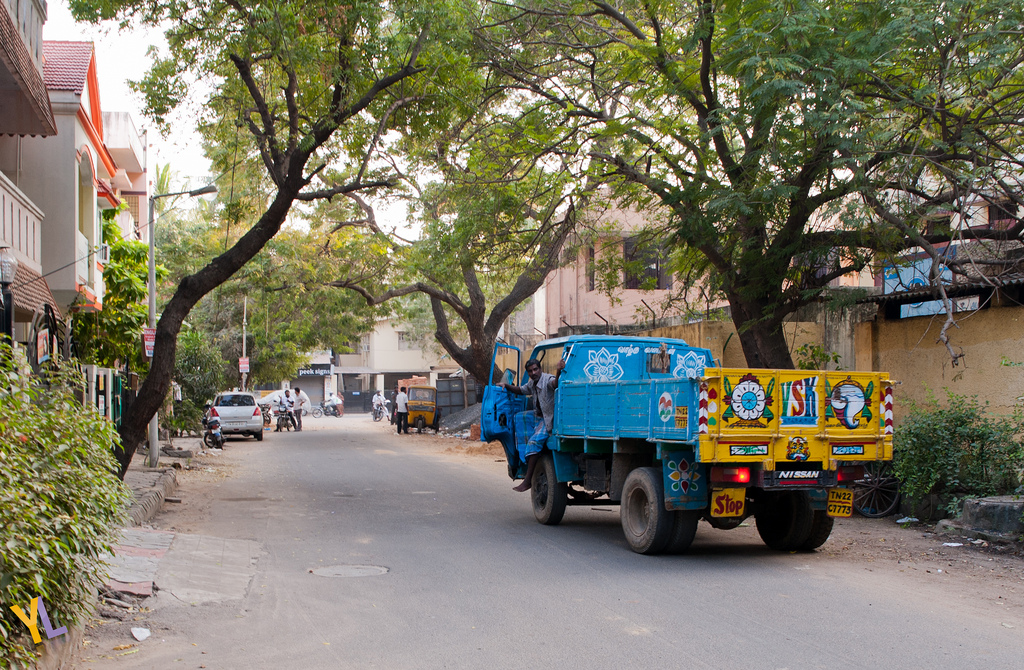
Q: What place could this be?
A: It is a road.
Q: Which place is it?
A: It is a road.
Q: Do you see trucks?
A: Yes, there is a truck.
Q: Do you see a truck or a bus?
A: Yes, there is a truck.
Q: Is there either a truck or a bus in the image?
A: Yes, there is a truck.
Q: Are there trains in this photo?
A: No, there are no trains.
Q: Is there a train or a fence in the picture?
A: No, there are no trains or fences.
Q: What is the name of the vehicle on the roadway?
A: The vehicle is a truck.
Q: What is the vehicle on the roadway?
A: The vehicle is a truck.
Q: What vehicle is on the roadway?
A: The vehicle is a truck.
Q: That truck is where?
A: The truck is on the roadway.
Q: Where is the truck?
A: The truck is on the roadway.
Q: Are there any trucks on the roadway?
A: Yes, there is a truck on the roadway.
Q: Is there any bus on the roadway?
A: No, there is a truck on the roadway.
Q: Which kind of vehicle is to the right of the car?
A: The vehicle is a truck.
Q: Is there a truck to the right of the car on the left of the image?
A: Yes, there is a truck to the right of the car.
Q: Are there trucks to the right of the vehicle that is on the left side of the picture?
A: Yes, there is a truck to the right of the car.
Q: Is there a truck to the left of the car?
A: No, the truck is to the right of the car.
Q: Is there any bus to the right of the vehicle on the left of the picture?
A: No, there is a truck to the right of the car.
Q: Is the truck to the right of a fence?
A: No, the truck is to the right of the car.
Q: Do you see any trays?
A: No, there are no trays.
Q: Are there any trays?
A: No, there are no trays.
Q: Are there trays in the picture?
A: No, there are no trays.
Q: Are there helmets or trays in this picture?
A: No, there are no trays or helmets.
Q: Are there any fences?
A: No, there are no fences.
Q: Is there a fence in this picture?
A: No, there are no fences.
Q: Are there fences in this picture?
A: No, there are no fences.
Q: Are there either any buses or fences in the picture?
A: No, there are no fences or buses.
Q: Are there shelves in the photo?
A: No, there are no shelves.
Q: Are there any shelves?
A: No, there are no shelves.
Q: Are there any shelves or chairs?
A: No, there are no shelves or chairs.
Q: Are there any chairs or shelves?
A: No, there are no shelves or chairs.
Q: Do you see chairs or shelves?
A: No, there are no shelves or chairs.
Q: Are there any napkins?
A: No, there are no napkins.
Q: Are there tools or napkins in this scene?
A: No, there are no napkins or tools.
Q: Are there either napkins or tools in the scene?
A: No, there are no napkins or tools.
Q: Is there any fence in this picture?
A: No, there are no fences.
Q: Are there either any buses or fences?
A: No, there are no fences or buses.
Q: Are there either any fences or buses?
A: No, there are no fences or buses.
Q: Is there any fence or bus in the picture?
A: No, there are no fences or buses.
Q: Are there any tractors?
A: No, there are no tractors.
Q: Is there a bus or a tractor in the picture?
A: No, there are no tractors or buses.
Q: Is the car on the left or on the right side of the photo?
A: The car is on the left of the image.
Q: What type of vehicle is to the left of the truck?
A: The vehicle is a car.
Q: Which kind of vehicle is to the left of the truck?
A: The vehicle is a car.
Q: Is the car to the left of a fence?
A: No, the car is to the left of the truck.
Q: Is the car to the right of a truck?
A: No, the car is to the left of a truck.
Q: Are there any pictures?
A: No, there are no pictures.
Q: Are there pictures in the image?
A: No, there are no pictures.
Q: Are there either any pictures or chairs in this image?
A: No, there are no pictures or chairs.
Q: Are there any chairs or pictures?
A: No, there are no pictures or chairs.